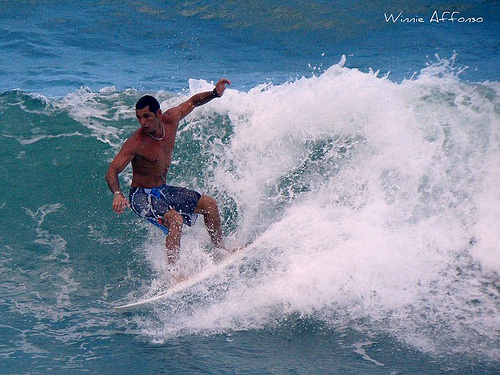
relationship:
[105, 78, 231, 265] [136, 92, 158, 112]
surfer has hair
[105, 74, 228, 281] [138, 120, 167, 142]
surfer wearing a necklace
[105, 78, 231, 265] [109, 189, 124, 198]
surfer wearing a watch